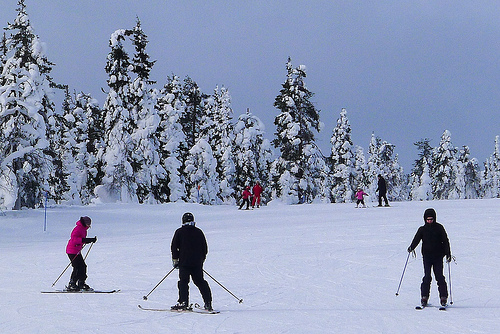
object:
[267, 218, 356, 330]
snow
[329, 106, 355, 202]
tree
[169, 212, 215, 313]
man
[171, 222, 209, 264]
jacket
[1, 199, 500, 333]
plain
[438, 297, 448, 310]
ski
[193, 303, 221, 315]
ski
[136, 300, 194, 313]
ski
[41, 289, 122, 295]
ski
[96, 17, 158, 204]
tree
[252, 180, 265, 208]
man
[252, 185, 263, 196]
jacket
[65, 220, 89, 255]
snow jacket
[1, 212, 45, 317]
snow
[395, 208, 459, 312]
skier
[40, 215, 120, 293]
skier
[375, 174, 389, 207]
skier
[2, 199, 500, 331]
hillside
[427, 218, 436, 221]
sunglasses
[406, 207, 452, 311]
person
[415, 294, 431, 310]
ski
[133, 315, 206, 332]
tracks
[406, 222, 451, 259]
jacket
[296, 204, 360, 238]
snow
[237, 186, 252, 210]
skier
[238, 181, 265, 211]
pair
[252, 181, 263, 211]
outfit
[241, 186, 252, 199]
outfit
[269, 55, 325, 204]
tree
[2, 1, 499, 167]
sky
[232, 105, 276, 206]
tree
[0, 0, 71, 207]
trees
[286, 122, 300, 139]
snow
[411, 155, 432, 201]
snow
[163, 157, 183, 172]
snow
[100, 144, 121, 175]
snow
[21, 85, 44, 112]
snow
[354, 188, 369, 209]
child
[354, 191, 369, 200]
jacket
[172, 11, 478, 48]
blue sky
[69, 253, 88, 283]
pants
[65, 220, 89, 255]
jacket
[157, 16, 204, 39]
clouds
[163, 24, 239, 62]
clouds